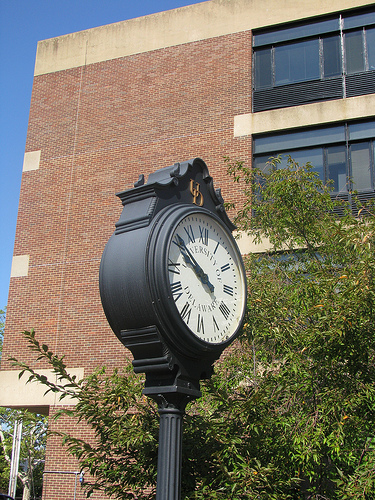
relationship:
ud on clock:
[189, 177, 212, 213] [164, 200, 253, 352]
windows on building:
[258, 29, 353, 117] [85, 69, 219, 156]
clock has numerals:
[164, 200, 253, 352] [205, 222, 215, 258]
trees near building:
[255, 214, 362, 482] [85, 69, 219, 156]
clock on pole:
[164, 200, 253, 352] [156, 390, 179, 499]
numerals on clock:
[205, 222, 215, 258] [164, 200, 253, 352]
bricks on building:
[161, 76, 199, 99] [85, 69, 219, 156]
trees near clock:
[255, 214, 362, 482] [164, 200, 253, 352]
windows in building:
[258, 29, 353, 117] [85, 69, 219, 156]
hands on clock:
[176, 236, 218, 294] [164, 200, 253, 352]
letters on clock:
[189, 177, 212, 213] [164, 200, 253, 352]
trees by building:
[255, 214, 362, 482] [85, 69, 219, 156]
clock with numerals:
[164, 200, 253, 352] [205, 222, 215, 258]